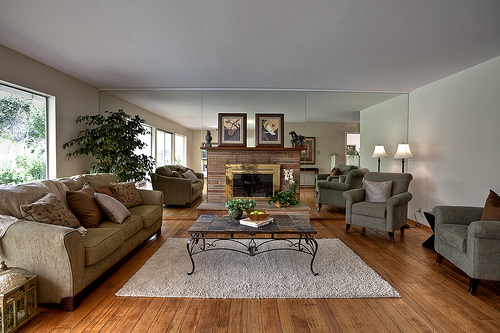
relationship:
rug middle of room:
[140, 216, 417, 321] [56, 73, 422, 314]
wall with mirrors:
[190, 116, 363, 194] [111, 80, 419, 236]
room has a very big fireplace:
[0, 1, 497, 331] [201, 149, 302, 204]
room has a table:
[0, 1, 497, 331] [186, 214, 318, 276]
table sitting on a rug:
[181, 209, 322, 277] [108, 231, 403, 304]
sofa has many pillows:
[1, 159, 180, 304] [24, 182, 146, 229]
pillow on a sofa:
[20, 193, 82, 229] [1, 174, 173, 310]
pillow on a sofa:
[65, 182, 109, 227] [1, 174, 173, 310]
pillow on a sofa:
[92, 190, 134, 222] [1, 174, 173, 310]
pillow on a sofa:
[110, 182, 144, 208] [1, 174, 173, 310]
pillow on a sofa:
[360, 174, 394, 206] [1, 174, 173, 310]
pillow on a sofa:
[107, 170, 145, 210] [1, 174, 173, 310]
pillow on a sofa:
[66, 183, 104, 228] [1, 174, 173, 310]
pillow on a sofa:
[15, 187, 86, 241] [1, 174, 173, 310]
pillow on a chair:
[364, 179, 392, 202] [342, 165, 415, 249]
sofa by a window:
[145, 160, 223, 202] [114, 120, 201, 177]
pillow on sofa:
[20, 193, 82, 229] [1, 174, 173, 310]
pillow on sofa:
[66, 183, 104, 228] [1, 174, 173, 310]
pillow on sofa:
[92, 190, 134, 222] [1, 174, 173, 310]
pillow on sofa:
[110, 182, 144, 208] [1, 174, 173, 310]